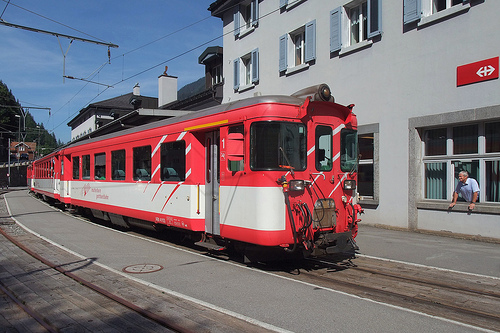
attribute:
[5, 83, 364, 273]
trolley — red and white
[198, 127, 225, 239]
doors — trolley entry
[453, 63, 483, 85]
sign — red , directional 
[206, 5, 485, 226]
building — large, white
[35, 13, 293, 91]
wires — overhead, electrical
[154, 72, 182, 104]
chimney — white and black